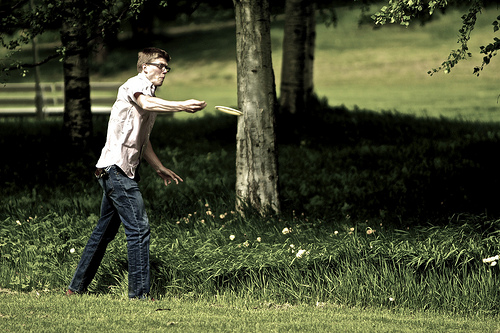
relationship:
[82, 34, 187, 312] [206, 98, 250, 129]
man throwing frisbee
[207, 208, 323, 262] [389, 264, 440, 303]
flowers in grass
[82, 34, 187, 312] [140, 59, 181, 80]
man wearing glasses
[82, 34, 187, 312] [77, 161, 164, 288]
man in blue jeans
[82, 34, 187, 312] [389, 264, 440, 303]
man standing in grass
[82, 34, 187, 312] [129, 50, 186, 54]
man has brown hair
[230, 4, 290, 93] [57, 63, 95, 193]
trunk of tree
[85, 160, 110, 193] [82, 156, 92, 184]
pocket flap in back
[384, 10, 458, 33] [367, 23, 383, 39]
leaves in sunlight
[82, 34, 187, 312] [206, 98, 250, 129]
man tossing frisbee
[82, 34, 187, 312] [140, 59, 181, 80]
man in glasses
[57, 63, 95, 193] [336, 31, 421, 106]
tree in park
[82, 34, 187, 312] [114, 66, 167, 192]
man wearing shirt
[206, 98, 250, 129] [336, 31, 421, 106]
frisbee in park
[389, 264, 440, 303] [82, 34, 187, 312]
grass by man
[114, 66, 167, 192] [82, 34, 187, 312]
shirt on man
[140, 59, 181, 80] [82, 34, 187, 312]
glasses on man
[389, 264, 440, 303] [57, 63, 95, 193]
grass under tree